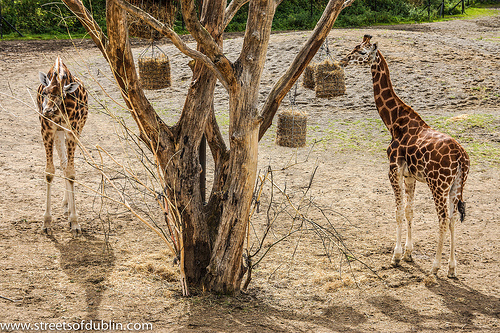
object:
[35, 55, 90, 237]
giraffe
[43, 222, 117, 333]
shadows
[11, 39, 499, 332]
ground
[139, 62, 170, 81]
hay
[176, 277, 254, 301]
base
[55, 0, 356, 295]
tree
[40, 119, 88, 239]
legs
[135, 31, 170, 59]
wire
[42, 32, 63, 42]
grass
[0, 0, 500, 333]
pasture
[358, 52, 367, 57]
eye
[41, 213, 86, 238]
feet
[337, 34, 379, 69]
head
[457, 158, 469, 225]
tail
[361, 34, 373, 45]
horns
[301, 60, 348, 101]
bag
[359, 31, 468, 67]
spots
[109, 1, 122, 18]
wood